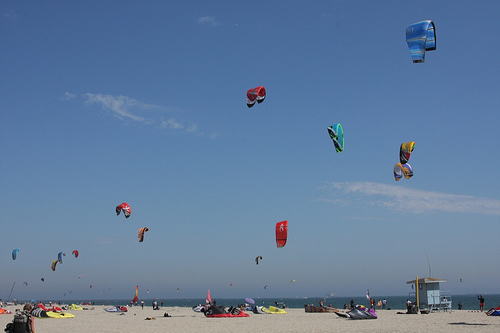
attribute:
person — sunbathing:
[23, 303, 67, 320]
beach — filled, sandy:
[2, 299, 497, 333]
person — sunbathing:
[204, 305, 241, 315]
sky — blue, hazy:
[1, 3, 499, 299]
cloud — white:
[319, 179, 499, 216]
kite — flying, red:
[275, 220, 288, 248]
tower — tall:
[406, 276, 452, 315]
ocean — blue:
[5, 298, 499, 312]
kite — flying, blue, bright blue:
[403, 17, 437, 65]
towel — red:
[205, 312, 251, 319]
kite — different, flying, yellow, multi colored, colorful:
[391, 139, 417, 182]